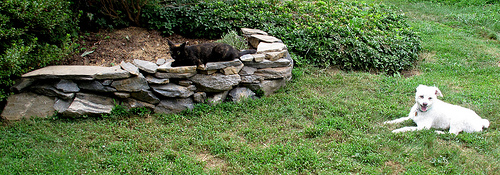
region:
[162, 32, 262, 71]
A can on the stone wall.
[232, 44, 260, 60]
the tail of a cat.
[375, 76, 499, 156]
A white dog.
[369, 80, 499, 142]
A dog on the grass.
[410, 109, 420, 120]
A tag on the collar.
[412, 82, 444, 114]
The dog is smiling.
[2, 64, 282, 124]
the stone wall of rocks.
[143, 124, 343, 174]
patches of dirt on the green.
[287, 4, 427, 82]
Bushes on the ground.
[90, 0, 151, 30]
Vines for the bush.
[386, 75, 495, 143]
a white dog in the grass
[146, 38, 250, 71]
a black and brown cat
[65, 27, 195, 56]
brown dirt behind a stone fence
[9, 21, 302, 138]
a circular shaped stone fence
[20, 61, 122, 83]
a long, thin, flat stone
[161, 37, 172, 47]
an ear on a cat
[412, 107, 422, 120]
a tag on a dad's neck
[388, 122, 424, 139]
a white front leg on a dog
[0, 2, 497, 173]
a grassy lawn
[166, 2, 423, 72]
green plants on the lawn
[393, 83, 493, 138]
White dog laying on grass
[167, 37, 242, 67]
Black cat laying on stone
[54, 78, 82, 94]
Small grey rock embedded into wall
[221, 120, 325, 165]
Area of fluffy green grass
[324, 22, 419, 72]
Long dark green shurbs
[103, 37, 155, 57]
Pile of dark brown dirt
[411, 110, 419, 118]
Gold name tag on dog collar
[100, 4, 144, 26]
Small brown branches on shrubs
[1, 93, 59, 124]
Large grey rock resting on ground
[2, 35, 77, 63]
Light green leaves on shrub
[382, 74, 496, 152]
This dog is sitting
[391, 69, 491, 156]
It has a collar on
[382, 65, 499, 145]
The dog is white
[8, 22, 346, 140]
A formation of rocks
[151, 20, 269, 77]
A black and brown cat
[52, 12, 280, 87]
Dirt in between the rocks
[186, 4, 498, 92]
Bushes by the rocks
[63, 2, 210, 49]
Tree branches by the dirt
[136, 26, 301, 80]
The cat is not looking at the camera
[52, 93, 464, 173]
The grass is cut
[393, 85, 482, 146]
the dog is white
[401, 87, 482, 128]
the dog is lying on the ground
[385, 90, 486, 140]
the mouth is open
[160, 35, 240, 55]
the cat is on the rocks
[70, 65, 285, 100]
the rocks are stacked together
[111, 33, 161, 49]
the ground is brown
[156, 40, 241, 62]
the cat is black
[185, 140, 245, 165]
patches are on the ground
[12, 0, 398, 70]
the bush is thick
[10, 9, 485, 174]
the scene is out doors